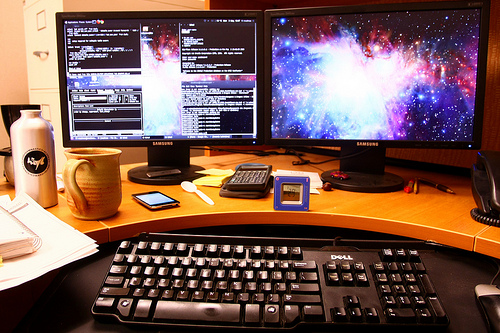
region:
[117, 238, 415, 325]
black keyboard on desk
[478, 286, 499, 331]
black and grey USB mouse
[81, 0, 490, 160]
two monitors on desk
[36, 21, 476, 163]
monitors have black frames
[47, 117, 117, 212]
brown mug on desk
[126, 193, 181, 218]
touch screen phone on desk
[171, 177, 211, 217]
white spoon on desk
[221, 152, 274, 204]
black calculator on desk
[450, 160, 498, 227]
black telephone on desk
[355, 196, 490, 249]
desk is dark brown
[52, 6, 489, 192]
two flat screen monitors set up side by side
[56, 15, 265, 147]
four windows with information in eatch pulled up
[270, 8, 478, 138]
nothing showing on screen except for the background picture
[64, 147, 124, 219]
coffee mug setting on desk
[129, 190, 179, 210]
cell phone is activated and lit up on desk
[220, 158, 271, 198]
calculator set up on desk for quick use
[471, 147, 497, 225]
telephone with cord attached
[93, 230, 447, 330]
dell computer keyboard on pull out desk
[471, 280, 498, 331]
mouse for computer to the right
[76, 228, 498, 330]
smaller pull out shelf for keyboard and mouse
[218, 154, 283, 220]
a black calculator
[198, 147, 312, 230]
a calculator on a desk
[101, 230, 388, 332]
a black keyboard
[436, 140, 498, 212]
a black cord phone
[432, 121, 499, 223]
a phone on a desk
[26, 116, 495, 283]
a brown computer desk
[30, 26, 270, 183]
a computer screen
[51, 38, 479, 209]
two computer screens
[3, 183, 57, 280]
a notebook on a desk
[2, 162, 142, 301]
white papers on a desk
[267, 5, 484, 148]
black samsung computer monitor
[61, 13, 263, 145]
samsung computer monitor that is black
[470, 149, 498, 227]
black phone on the desk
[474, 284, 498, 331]
computer mouse on the desk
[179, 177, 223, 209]
a white plastic spoon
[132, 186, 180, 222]
cell phone on desk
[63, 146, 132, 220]
coffee mug on desk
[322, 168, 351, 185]
red toy car on monitor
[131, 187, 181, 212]
a cellphone on a desk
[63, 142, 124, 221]
a coffee cup on a desk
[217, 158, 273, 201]
a calculator on a desk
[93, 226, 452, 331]
a black computer keyboard on a desk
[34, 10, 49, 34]
a picture in a frame on a wall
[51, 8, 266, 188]
a computer monitor on a desk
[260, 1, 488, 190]
a computer monitor on a desk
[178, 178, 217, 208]
a plastic spoon on a desk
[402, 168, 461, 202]
pencils and pens on a desk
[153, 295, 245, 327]
the space bar on a keyboard